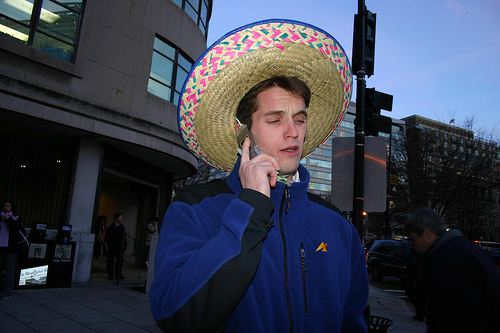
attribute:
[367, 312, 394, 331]
bin — garbage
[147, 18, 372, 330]
man — STRAW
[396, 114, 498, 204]
building — distant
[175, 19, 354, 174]
hat — straw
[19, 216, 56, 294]
newpaper bin — newspaper, distant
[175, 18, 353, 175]
straw hat — straw 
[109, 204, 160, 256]
jacket — black 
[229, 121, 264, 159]
phone — silver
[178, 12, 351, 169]
hat — straw , MULTI COLORED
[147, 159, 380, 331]
jacket — multiple colored, man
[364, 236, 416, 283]
vehicle — dark 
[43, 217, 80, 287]
newspaper box — black , metal 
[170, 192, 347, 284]
jacket — blue , black 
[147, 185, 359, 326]
jacket — blue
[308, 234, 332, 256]
insignia — yellow 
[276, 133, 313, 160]
mouth — half open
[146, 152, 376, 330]
shirt — blue 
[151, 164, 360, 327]
stripes — black 